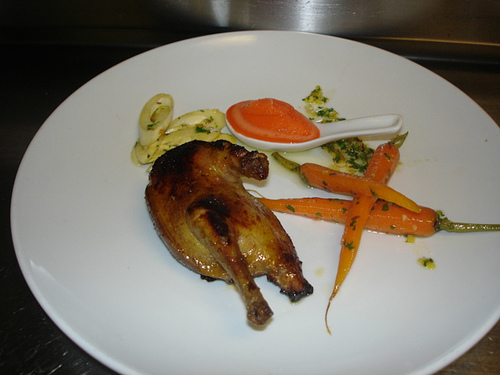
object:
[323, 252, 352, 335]
tip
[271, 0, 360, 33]
light shining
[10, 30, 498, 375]
dish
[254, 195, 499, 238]
carrot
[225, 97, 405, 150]
spoon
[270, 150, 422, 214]
carrots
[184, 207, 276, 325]
leg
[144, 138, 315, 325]
chicken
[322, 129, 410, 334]
carrot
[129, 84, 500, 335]
foods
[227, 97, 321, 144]
food stuff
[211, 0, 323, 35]
light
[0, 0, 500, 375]
table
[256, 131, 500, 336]
sprinklings